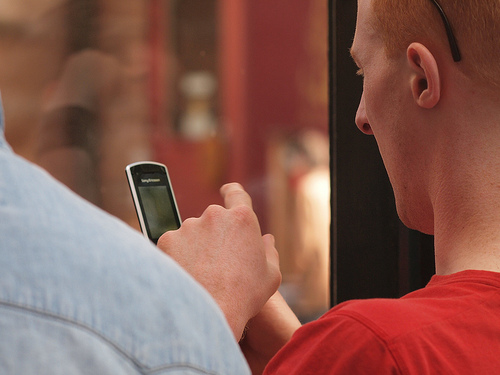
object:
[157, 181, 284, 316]
hand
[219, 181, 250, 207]
finger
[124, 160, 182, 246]
cell phone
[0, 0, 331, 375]
window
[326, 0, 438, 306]
black border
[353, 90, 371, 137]
nose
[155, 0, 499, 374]
man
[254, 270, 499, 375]
shirt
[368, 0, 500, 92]
hair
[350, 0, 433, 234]
face